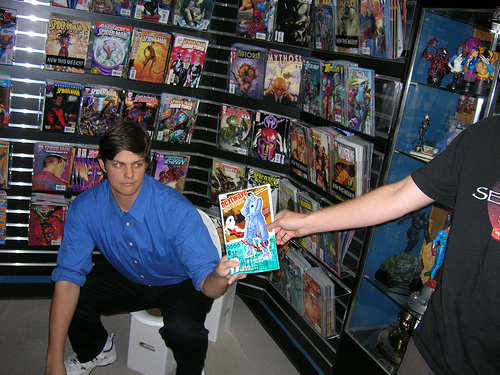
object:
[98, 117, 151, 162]
hair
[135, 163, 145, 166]
eyes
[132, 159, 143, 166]
eyebrows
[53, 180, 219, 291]
shirt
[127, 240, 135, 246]
buttons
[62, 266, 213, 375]
pants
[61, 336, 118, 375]
sneakers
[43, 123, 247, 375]
man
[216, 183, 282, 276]
comic book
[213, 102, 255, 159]
magazines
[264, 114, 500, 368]
man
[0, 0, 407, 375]
racks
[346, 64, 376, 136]
comic books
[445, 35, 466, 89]
figures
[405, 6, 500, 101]
shelf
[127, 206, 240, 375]
toilet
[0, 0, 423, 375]
display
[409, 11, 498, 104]
display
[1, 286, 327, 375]
floor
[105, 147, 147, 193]
face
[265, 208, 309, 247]
hand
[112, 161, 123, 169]
eye